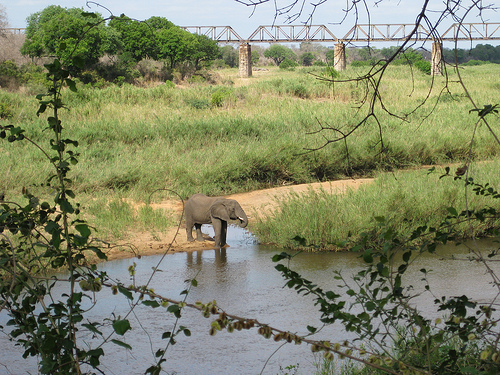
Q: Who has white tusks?
A: The elephant.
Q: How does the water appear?
A: Calm.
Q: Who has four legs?
A: Elephant.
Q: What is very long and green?
A: The grass.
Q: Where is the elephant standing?
A: Near the water.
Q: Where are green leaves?
A: On trees.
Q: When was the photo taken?
A: During the daytime.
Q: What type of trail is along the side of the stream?
A: Dirt.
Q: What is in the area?
A: Tall weeds and grass.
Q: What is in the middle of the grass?
A: Water.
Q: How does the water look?
A: Dark brown in color.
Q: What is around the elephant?
A: Dirt.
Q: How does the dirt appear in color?
A: Tan.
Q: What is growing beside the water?
A: Grass.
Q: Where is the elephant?
A: By the river.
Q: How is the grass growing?
A: Tall and green.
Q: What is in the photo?
A: An elephant.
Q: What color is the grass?
A: Green.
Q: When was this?
A: Daytime.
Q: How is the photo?
A: Clear.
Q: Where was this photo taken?
A: At a zoo.